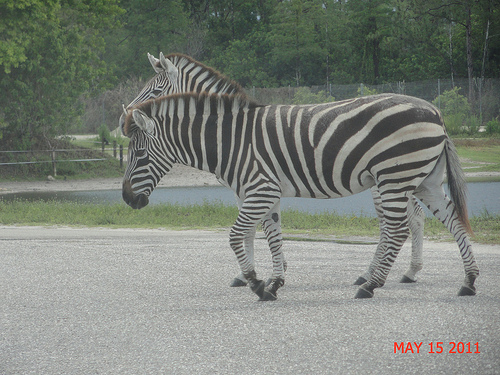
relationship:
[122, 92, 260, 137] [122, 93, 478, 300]
mane on zebra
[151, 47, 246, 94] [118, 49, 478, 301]
mane on zebra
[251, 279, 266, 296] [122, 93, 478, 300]
hoof on zebra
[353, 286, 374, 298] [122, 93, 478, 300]
hoof on zebra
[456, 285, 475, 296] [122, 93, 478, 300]
hoof on zebra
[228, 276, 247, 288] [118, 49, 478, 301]
hoof on zebra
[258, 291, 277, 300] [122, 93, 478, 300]
hoof on zebra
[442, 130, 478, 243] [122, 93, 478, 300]
tail on zebra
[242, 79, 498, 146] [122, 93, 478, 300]
fence behind zebra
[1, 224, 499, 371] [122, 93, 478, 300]
pavement under zebra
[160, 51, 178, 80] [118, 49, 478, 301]
ear on zebra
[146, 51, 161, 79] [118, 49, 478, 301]
ear on zebra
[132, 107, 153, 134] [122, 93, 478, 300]
ear on zebra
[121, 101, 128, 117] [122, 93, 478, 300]
ear on zebra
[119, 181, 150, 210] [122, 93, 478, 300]
nose on zebra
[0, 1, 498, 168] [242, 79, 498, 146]
trees behind fence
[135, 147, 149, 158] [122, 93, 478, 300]
eye on zebra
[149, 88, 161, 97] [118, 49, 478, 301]
eye on zebra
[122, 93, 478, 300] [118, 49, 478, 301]
zebra by zebra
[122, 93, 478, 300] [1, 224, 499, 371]
zebra on pavement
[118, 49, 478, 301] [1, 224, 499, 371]
zebra on pavement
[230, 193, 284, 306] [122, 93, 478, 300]
legs of zebra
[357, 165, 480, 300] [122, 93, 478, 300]
legs of zebra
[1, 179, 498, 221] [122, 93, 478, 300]
water by zebra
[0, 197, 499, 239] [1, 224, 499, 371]
grass by pavement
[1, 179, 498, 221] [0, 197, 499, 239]
water by grass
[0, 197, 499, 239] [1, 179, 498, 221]
grass by water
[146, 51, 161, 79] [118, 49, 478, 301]
ear of zebra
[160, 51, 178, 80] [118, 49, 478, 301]
ear of zebra